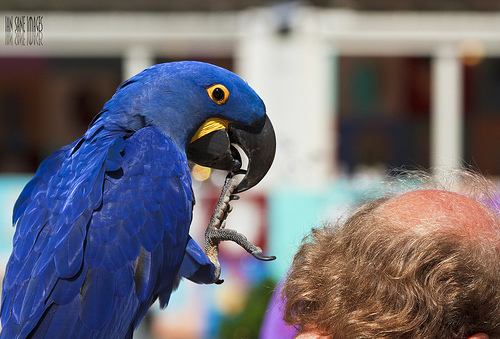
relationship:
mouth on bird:
[180, 117, 281, 192] [0, 60, 275, 339]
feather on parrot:
[58, 183, 148, 333] [36, 18, 293, 337]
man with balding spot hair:
[272, 173, 482, 337] [347, 266, 413, 308]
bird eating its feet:
[7, 30, 289, 336] [207, 165, 264, 276]